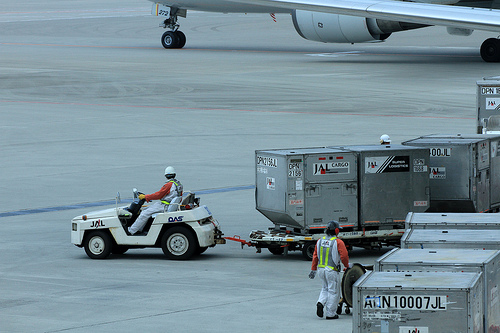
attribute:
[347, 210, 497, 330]
tank — silver  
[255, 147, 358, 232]
containers — silver, grey, metal 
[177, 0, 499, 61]
plane — white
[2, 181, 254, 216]
line — blue 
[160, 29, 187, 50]
wheels — black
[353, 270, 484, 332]
silver tank — grey, metal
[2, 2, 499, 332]
road — gray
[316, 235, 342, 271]
vest — neon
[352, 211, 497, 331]
boxes — silver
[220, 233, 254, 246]
hook — red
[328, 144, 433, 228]
canister — grey